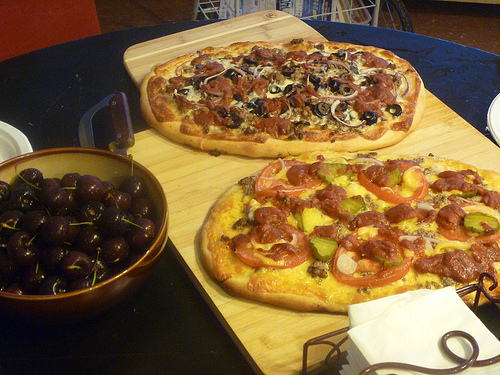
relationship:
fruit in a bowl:
[8, 169, 149, 291] [9, 127, 149, 339]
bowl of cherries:
[5, 141, 178, 313] [2, 168, 159, 295]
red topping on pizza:
[354, 228, 401, 265] [130, 17, 425, 156]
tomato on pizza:
[229, 217, 311, 279] [130, 17, 425, 156]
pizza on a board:
[127, 37, 433, 162] [115, 74, 499, 372]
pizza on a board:
[193, 151, 498, 299] [115, 74, 499, 372]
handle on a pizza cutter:
[110, 96, 132, 148] [28, 71, 170, 183]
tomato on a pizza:
[234, 224, 314, 270] [193, 151, 498, 299]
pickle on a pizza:
[462, 211, 494, 238] [195, 149, 498, 317]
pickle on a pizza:
[341, 190, 363, 212] [195, 149, 498, 317]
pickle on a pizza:
[305, 234, 334, 259] [195, 149, 498, 317]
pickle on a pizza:
[339, 184, 370, 214] [195, 149, 498, 317]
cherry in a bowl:
[42, 210, 75, 242] [5, 141, 178, 313]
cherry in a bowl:
[60, 246, 95, 286] [0, 147, 167, 312]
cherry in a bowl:
[41, 211, 72, 246] [0, 147, 167, 312]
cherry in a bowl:
[75, 170, 106, 202] [0, 147, 167, 312]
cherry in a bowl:
[12, 166, 43, 187] [0, 147, 167, 312]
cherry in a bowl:
[128, 213, 156, 247] [0, 147, 167, 312]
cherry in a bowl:
[57, 168, 109, 209] [0, 147, 167, 312]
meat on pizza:
[172, 50, 403, 140] [127, 37, 433, 162]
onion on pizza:
[166, 45, 412, 135] [127, 37, 433, 162]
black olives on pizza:
[172, 41, 409, 140] [127, 37, 433, 162]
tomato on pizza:
[234, 224, 314, 270] [193, 151, 498, 299]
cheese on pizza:
[266, 156, 467, 275] [193, 151, 498, 299]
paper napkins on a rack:
[331, 287, 498, 363] [298, 275, 497, 372]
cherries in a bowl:
[1, 169, 150, 286] [1, 143, 173, 322]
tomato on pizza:
[252, 156, 323, 198] [195, 149, 498, 317]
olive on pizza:
[360, 110, 375, 125] [127, 37, 433, 162]